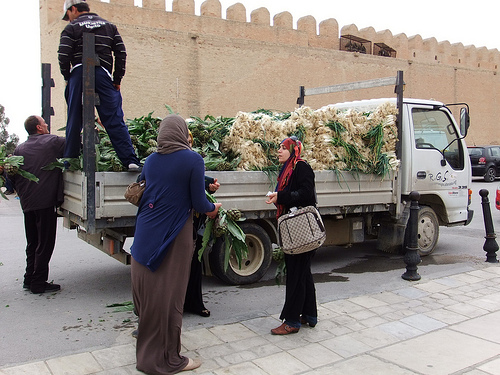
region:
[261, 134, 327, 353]
Woman with a head scarf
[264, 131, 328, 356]
Woman standing in street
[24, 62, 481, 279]
Truck full of a plant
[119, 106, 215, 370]
Woman standing in street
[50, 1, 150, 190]
Man standing in truck bed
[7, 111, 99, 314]
Man putting something into truck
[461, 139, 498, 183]
Car driving on the street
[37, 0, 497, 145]
A brick wall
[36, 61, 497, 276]
Parked truck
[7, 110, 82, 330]
Man wearing gray jacket and black pants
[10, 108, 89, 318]
man wearing dark shoes standing on pavement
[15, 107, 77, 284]
man wearing dark pants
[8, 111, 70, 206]
man wearing dark jacket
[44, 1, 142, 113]
man wearing white baseball cap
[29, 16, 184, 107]
man wearing black jacket with white lettering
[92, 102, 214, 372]
lady wearing brown scarf on her head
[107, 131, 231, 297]
woman wearing blue sweater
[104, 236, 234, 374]
woman wearing brown skirt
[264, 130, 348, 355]
woman wearing multi color scarf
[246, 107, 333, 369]
woman carrying a carryall bag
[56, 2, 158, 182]
Person is on top of a truck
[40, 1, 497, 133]
A beige building is in the background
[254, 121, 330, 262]
Woman is holding a purse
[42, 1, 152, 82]
Man is wearing a gray cap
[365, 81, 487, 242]
The front of the truck is white in color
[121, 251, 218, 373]
Bottom of woman's dress is brown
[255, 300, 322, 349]
Woman is wearing brown shoes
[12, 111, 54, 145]
Man has short dark hair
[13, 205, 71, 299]
Man has black pants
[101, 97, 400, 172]
Truck is carrying a supply of plants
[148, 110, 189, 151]
Lady with brown scarf on her head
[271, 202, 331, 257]
Purse on left arm of lady with red scraf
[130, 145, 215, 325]
Lady wearing blue coat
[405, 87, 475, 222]
Passenger door of truck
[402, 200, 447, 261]
Right front wheel of truck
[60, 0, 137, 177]
Man standingon bed with blue work clothes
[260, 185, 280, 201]
Left hand of woman with red scraf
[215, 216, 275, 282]
Back right tire of truck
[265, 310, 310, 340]
Left foot with brown shoe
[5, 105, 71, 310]
Man standing at back of truck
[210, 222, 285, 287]
The back wheels on the truck.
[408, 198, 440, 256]
The front wheel of the truck.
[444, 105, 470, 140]
The side view mirror on the truck.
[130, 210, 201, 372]
The gray skirt the woman is wearing.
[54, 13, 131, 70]
The black and white sweater the man is wearing.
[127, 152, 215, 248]
The blue sweater the lady is wearing.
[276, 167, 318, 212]
The black jacket the lady is wearing.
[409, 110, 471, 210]
The door of the truck.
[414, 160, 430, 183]
The door handle on the truck's door.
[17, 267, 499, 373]
The sidewalk where the ladies are standing.